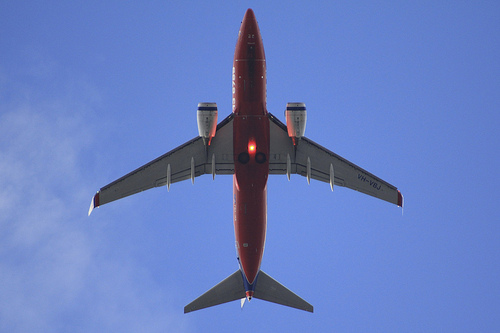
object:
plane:
[87, 7, 409, 315]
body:
[232, 7, 269, 301]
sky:
[0, 0, 499, 332]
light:
[248, 138, 258, 158]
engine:
[284, 101, 307, 146]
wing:
[84, 114, 235, 215]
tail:
[182, 268, 312, 318]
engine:
[193, 98, 222, 153]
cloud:
[1, 82, 197, 331]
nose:
[234, 7, 265, 45]